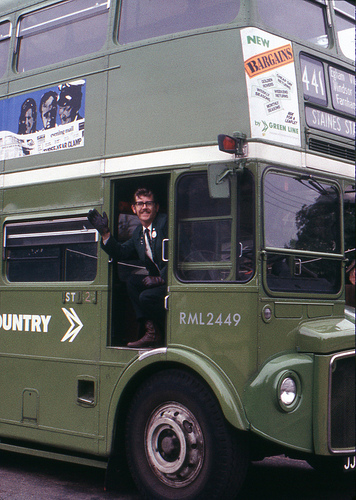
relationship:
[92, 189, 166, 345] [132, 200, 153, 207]
man wears glasses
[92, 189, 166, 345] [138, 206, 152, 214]
man has mustache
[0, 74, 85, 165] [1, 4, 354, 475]
ad on bus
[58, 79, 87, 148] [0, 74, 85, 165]
person on ad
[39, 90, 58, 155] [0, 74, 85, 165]
person on ad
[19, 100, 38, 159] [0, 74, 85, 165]
person on ad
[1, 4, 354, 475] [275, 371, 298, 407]
bus has headlight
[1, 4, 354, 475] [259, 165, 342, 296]
bus has windshield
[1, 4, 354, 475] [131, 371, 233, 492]
bus has wheel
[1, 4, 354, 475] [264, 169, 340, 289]
bus has window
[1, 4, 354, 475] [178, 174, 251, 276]
bus has window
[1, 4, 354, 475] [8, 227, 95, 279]
bus has window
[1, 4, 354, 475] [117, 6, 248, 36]
bus has window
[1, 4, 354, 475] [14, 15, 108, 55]
bus has window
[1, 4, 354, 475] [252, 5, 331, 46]
bus has window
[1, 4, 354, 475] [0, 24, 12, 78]
bus has window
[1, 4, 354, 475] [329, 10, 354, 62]
bus has window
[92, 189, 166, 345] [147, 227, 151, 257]
man wears tie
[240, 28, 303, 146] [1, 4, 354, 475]
ad on bus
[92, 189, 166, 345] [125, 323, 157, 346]
man wears boot